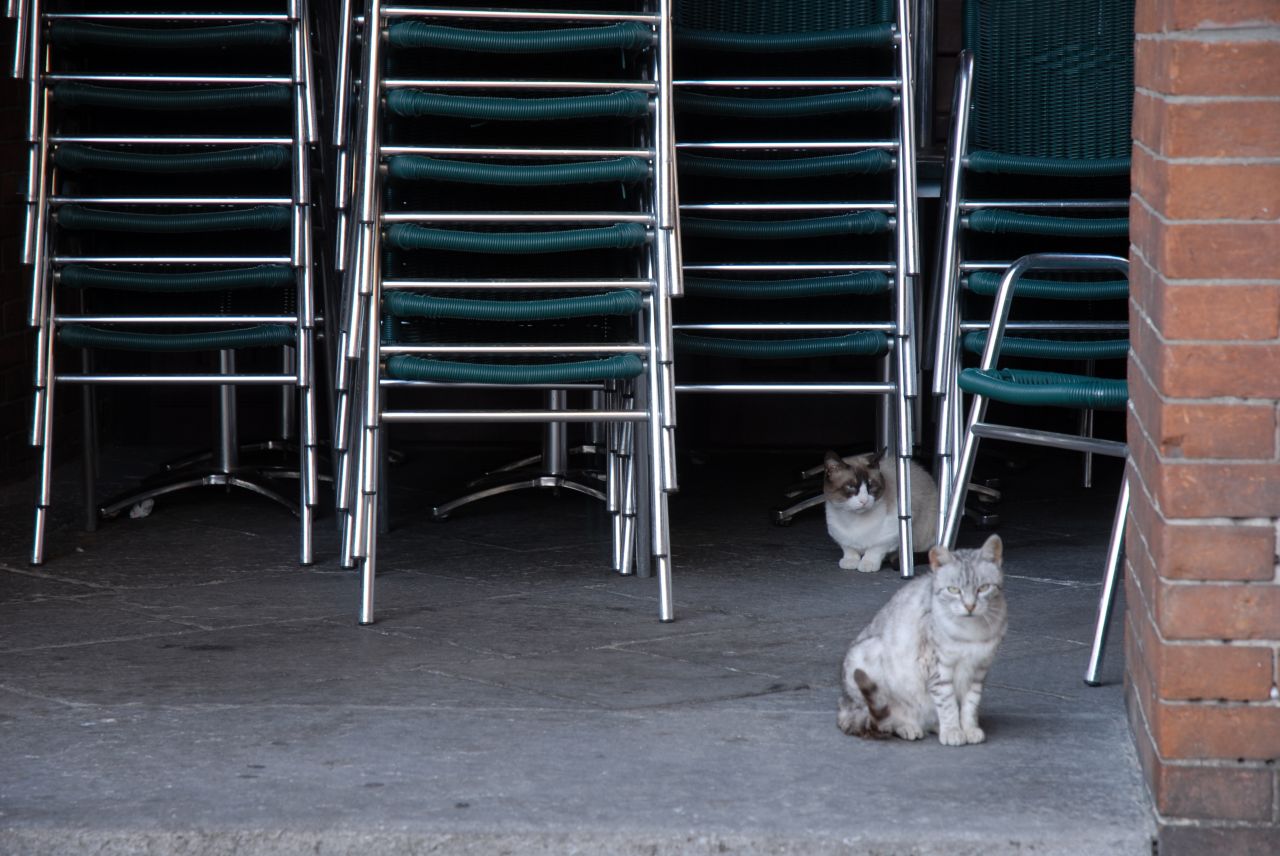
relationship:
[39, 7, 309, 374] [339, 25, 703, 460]
seats are on chair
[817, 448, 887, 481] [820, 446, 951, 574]
ears are on cat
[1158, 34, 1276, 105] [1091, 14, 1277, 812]
brick in wall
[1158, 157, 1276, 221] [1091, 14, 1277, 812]
brick in wall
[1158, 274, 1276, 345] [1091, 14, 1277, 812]
brick in wall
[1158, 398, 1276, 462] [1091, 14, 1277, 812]
brick in wall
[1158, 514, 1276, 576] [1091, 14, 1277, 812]
brick in wall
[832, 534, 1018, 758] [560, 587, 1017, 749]
cat on concrete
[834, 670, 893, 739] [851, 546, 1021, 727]
tail on cat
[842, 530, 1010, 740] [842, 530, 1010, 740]
rings on tail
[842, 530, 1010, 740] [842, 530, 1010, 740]
tail on cat